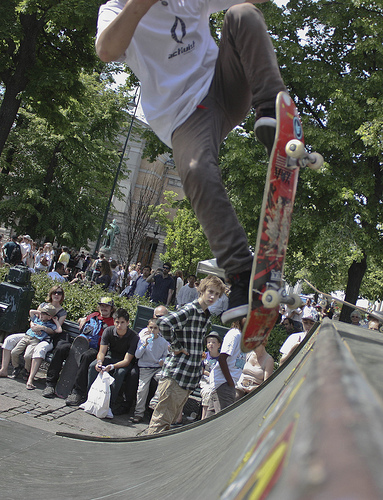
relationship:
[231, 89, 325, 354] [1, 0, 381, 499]
skateboard floating in air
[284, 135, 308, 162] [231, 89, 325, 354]
wheel of skateboard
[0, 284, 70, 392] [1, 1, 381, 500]
spectator inside skateboarding show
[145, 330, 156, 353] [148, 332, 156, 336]
bottled water inside mouth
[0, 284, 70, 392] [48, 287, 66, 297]
spectator wearing sunglasses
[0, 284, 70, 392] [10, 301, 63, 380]
spectator holding kid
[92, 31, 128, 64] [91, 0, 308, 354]
elbow of a guy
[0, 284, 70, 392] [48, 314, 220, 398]
spectator sitting on bench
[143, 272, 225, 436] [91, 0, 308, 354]
boy watching guy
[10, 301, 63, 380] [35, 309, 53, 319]
kid wearing sunglasses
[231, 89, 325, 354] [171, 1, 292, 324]
skateboard between legs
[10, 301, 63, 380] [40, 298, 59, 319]
kid wearing a hat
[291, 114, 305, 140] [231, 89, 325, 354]
sticker on underside of skateboard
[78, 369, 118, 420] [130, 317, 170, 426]
bag sitting by boy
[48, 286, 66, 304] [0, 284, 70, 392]
face of spectator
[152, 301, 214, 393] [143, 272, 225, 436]
shirt of boy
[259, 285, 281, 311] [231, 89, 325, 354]
wheel of skateboard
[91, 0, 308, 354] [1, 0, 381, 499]
guy skating in air